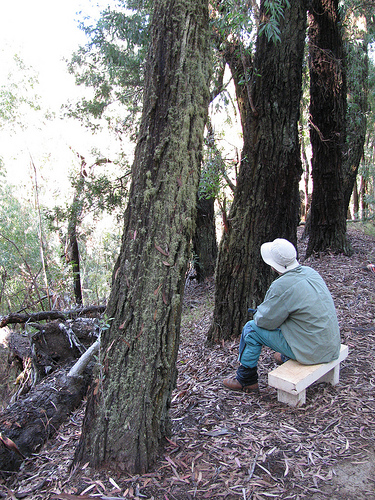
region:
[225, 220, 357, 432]
man sitting on the bench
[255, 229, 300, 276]
the hat is white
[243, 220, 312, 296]
the hat is white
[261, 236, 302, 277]
man wearing white hat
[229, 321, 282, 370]
man wearing blue jeans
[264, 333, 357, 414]
man sitting on small white bench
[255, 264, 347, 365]
man wearing blue shirt